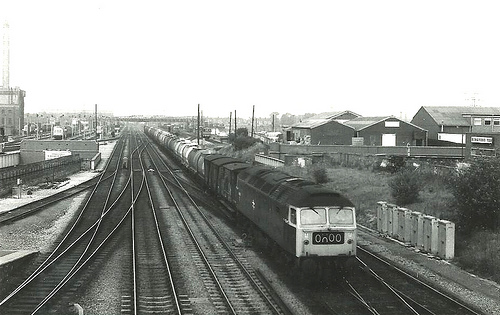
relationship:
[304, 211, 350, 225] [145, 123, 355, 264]
windows on train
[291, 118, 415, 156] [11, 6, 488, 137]
storage in distance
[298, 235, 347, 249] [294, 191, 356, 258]
letter on front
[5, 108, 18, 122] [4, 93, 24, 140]
brick on building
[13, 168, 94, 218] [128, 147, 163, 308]
platform off track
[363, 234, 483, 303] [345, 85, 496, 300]
gravel on side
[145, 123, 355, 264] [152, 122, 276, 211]
train has cars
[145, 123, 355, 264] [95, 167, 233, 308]
train on rail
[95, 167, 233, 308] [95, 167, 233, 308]
rail on rail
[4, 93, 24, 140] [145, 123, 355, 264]
building near train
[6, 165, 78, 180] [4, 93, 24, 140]
fence near building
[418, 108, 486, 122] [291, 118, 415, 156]
roof on storage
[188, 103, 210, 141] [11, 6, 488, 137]
pole in distance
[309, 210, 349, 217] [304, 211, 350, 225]
wipers on windows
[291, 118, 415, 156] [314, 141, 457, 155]
storage behind fence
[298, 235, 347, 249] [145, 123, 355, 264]
letter on train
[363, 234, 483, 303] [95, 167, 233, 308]
gravel around rail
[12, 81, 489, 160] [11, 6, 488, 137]
buildings in background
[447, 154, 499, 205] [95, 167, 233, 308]
bush near rail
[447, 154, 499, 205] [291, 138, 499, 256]
bush on ground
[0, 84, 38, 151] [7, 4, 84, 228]
tower on side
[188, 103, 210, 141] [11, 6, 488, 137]
pole in backgorund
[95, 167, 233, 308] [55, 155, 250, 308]
rail on ground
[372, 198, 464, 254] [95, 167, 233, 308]
boxes near rail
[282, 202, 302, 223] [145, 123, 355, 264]
window on train